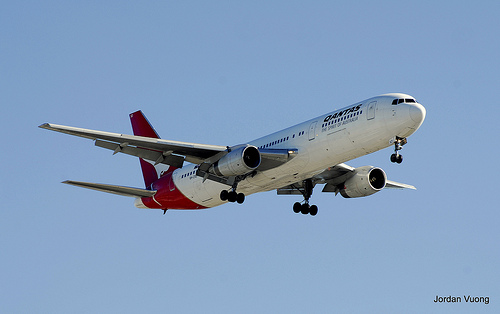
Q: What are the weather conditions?
A: It is clear.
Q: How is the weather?
A: It is clear.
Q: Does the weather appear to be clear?
A: Yes, it is clear.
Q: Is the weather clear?
A: Yes, it is clear.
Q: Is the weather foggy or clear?
A: It is clear.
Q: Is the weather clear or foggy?
A: It is clear.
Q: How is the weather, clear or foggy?
A: It is clear.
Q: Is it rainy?
A: No, it is clear.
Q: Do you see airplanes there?
A: Yes, there is an airplane.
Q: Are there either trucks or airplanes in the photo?
A: Yes, there is an airplane.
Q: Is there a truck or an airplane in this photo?
A: Yes, there is an airplane.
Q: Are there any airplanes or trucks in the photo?
A: Yes, there is an airplane.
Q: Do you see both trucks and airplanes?
A: No, there is an airplane but no trucks.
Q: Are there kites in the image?
A: No, there are no kites.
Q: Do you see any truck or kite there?
A: No, there are no kites or trucks.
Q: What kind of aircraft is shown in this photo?
A: The aircraft is an airplane.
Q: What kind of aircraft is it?
A: The aircraft is an airplane.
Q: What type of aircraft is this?
A: This is an airplane.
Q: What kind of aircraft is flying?
A: The aircraft is an airplane.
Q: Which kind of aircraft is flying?
A: The aircraft is an airplane.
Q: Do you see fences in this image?
A: No, there are no fences.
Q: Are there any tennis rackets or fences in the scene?
A: No, there are no fences or tennis rackets.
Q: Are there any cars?
A: No, there are no cars.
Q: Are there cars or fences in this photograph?
A: No, there are no cars or fences.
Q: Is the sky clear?
A: Yes, the sky is clear.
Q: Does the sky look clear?
A: Yes, the sky is clear.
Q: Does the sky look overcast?
A: No, the sky is clear.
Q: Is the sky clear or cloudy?
A: The sky is clear.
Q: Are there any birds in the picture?
A: No, there are no birds.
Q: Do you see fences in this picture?
A: No, there are no fences.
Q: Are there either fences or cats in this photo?
A: No, there are no fences or cats.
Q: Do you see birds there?
A: No, there are no birds.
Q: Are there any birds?
A: No, there are no birds.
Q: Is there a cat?
A: No, there are no cats.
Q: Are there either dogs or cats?
A: No, there are no cats or dogs.